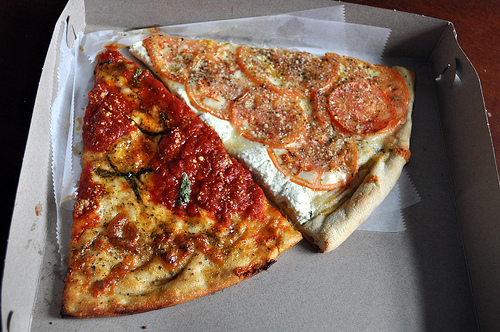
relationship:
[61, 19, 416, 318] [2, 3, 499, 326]
pizza in box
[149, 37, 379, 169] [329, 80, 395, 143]
seasoning on top of tomato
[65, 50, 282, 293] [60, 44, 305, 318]
cheese on pizza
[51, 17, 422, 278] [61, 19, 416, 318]
parchment paper under pizza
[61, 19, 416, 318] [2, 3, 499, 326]
two slices of pizza are in box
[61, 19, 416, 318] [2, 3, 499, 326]
pizza in a box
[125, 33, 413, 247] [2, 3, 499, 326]
pizza in box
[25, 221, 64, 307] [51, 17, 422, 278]
splat of grease on parchment paper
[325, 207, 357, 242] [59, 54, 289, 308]
crust of a pizza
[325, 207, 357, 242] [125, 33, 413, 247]
crust of a pizza